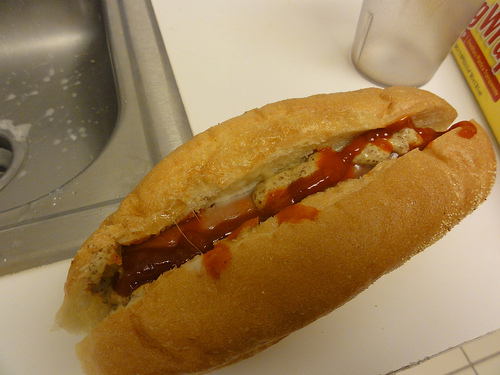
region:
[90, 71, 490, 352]
There is a hot dog on the counter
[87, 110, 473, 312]
There is ketchup on the hot dog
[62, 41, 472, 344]
There is mustard on the hot dog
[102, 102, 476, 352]
The hot dog is in a bun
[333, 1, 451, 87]
There is an empty cup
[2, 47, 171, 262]
There are suds in the sink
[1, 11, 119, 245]
The sink is empty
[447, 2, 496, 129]
There is cling wrap in the corner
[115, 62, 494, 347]
The hot dog is uneaten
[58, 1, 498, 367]
The counter is white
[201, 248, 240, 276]
red sauce on the bun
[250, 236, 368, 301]
a golden hot dog bun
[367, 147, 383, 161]
yellow hot mustard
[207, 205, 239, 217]
a long meaty hot dog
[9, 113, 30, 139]
white suds in the sink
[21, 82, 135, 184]
a stainless steel sink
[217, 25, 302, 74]
a white formica counter top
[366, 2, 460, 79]
an empty glass on the counter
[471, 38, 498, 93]
a yellow and red box of plastic wrap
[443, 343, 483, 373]
white tile around the sink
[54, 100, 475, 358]
sandwich on a bun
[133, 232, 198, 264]
barbecue sauce on a sandwich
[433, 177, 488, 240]
seeds on a bun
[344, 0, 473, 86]
empty plastic glass on counter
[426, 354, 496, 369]
white tile on a counter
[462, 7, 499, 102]
yellow box of cling wrap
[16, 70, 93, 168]
soap bubbles in the sink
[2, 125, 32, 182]
sink drain in the sink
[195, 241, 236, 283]
barbecue sauce on the bread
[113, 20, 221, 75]
stainless steel sink edge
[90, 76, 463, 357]
sandwich in a bun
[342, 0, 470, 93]
empty plastic cup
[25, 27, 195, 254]
silver sink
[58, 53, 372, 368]
sandwhich on counter next to sink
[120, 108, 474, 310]
red ketchup on top of sandwich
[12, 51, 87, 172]
bubbles at the bottom of the sink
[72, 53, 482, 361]
sandwich on top of white counter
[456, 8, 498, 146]
yellow box with red lettering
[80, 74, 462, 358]
hot dog with mustard and ketchup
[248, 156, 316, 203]
yellow mustard and ketchup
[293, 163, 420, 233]
Red sauce on the sandwich.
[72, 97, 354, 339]
sandwich on the plate.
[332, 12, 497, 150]
Cup in the background.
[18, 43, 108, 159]
Bubbles in the sink.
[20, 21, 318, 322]
Sink on the counter.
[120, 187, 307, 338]
Bread on the sandwich.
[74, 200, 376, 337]
Red sauce on the bread.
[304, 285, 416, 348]
White counter under the sandwich.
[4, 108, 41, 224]
Drain in the sink.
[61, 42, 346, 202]
Silver sink on the counter.